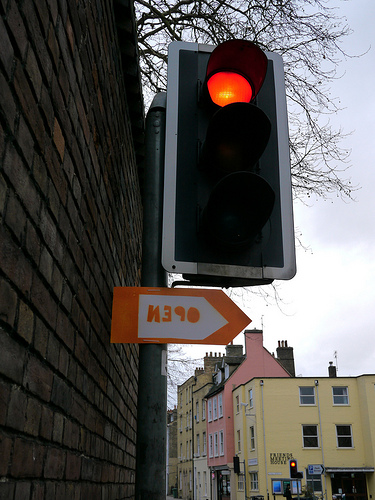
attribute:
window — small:
[245, 387, 257, 411]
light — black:
[205, 52, 258, 102]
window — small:
[244, 425, 259, 456]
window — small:
[235, 428, 243, 452]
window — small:
[235, 394, 240, 415]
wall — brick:
[1, 107, 82, 261]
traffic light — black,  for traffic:
[167, 40, 297, 281]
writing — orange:
[146, 303, 201, 323]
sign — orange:
[110, 285, 251, 344]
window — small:
[300, 422, 319, 449]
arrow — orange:
[107, 287, 255, 350]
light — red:
[205, 67, 253, 118]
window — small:
[297, 383, 318, 409]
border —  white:
[159, 38, 191, 283]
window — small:
[213, 388, 226, 415]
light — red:
[191, 42, 262, 112]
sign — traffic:
[169, 35, 299, 277]